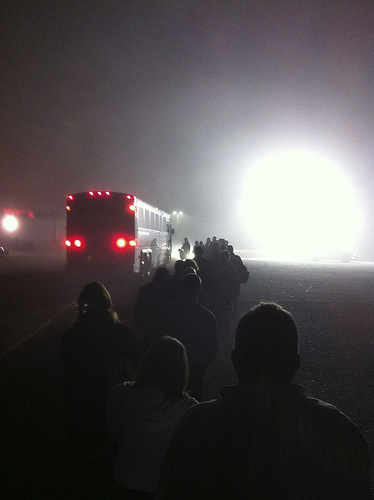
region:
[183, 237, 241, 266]
Heads of people in the dark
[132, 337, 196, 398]
Back of a head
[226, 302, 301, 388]
A mans back of the head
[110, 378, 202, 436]
woman's hood of a jacket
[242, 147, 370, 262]
Large white illumination of light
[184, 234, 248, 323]
Group of people in the dark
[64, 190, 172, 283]
Bus in the dark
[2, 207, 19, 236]
Small round light illumination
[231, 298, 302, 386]
Back of a mans head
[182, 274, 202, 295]
Back of a mans head in the dark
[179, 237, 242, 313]
Group of people walking in the night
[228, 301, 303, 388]
back of a mans head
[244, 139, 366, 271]
bright white illumination in distance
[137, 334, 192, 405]
Back of a woman's head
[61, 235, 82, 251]
Red and white tail lights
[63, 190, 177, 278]
Bus sitting in the dark with lights on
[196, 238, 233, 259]
Heads of various people walking at night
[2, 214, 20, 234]
Small round light illuminating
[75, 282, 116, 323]
Back of a persons head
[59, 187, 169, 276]
a bus driving in the night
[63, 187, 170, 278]
the bus has brake lights on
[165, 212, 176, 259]
the rear view mirror on the bus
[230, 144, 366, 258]
a bright white light in the background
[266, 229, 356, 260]
a vehicle on front of a bright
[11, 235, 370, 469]
people waiting in line to board the bus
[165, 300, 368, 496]
a man standing in the dark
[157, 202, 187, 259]
street lights on in front of the bus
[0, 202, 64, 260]
a building behind a white light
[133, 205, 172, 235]
dark windows on the side of the bus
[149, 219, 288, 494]
people standing in line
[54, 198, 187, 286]
people waiting to get on a bus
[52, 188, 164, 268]
red lights on bus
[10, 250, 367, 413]
it is dark outside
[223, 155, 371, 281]
bright glowing light in the background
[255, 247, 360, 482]
the ground is dark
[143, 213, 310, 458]
people waiting in line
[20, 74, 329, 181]
the sky is black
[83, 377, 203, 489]
woman wearing light colored jacket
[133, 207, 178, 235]
many windows on the side of the bus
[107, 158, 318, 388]
People loading up on the bus.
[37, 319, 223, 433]
People in the dark.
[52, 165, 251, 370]
People traveling at night.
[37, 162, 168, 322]
Lights on the bus.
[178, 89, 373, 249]
Bright lights shining on people.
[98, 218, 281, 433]
People in line.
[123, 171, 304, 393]
People traveling at night.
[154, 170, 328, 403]
A group of people traveling at night.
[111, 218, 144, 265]
Parking lights on the back of bus.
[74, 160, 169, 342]
Red lights.